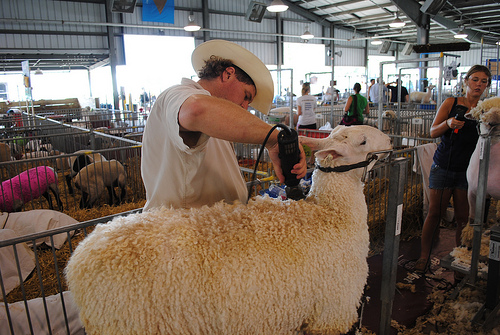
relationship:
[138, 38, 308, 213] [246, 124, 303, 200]
man using electric shears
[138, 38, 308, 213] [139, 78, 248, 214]
man wearing shirt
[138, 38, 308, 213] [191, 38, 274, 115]
man wearing hat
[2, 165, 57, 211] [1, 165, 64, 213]
blanket on sheep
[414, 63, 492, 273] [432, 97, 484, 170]
woman wearing tank top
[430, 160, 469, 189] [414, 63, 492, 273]
shorts on woman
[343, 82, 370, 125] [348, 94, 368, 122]
woman wearing shirt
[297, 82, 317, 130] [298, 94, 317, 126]
woman wearing shirt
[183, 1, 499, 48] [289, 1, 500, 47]
lights hanging from ceiling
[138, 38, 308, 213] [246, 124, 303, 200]
man holding electric shears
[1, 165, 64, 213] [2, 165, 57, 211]
sheep with blanket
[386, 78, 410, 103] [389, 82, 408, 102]
woman wearing shirt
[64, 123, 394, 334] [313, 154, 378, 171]
sheep wearing harness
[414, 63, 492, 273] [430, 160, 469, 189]
woman wearing shorts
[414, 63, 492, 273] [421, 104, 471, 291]
woman holding electric shears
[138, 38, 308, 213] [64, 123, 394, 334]
man shearing sheep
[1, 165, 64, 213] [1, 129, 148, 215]
sheep in holding pen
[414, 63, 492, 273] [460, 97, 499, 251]
woman shearing sheep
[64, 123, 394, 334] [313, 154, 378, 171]
sheep held by harness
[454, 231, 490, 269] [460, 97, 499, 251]
wool from sheep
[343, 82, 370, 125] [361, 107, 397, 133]
woman looking at sheep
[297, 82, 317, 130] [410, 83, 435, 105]
woman looking at sheep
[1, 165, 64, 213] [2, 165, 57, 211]
sheep in blanket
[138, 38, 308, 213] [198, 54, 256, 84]
man has hair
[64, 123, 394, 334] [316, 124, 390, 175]
sheep has head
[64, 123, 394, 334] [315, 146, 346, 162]
sheep has ear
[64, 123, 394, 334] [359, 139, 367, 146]
sheep has eye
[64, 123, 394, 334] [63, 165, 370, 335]
sheep has wool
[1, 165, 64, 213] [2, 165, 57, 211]
sheep wearing blanket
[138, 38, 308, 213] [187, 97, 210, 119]
man has elbow